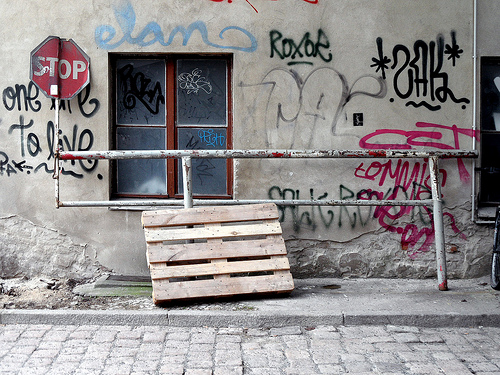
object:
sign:
[30, 35, 91, 99]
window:
[110, 54, 235, 201]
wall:
[1, 1, 496, 277]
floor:
[0, 322, 500, 374]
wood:
[139, 202, 293, 301]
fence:
[55, 150, 479, 289]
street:
[1, 325, 496, 374]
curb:
[1, 312, 499, 324]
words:
[269, 30, 285, 60]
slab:
[89, 279, 152, 295]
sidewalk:
[1, 278, 497, 315]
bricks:
[142, 331, 166, 342]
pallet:
[142, 204, 293, 301]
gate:
[55, 149, 478, 292]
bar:
[55, 150, 478, 159]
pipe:
[469, 1, 480, 225]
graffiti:
[178, 67, 214, 93]